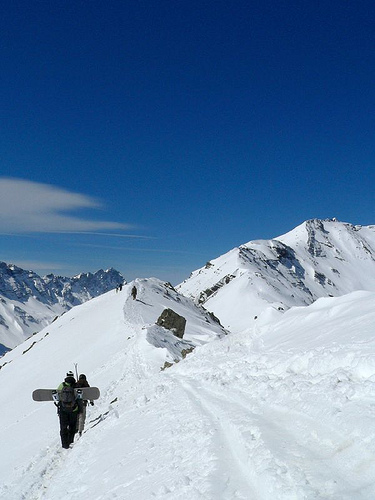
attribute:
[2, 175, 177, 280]
cloud — white 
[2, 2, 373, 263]
sky — beautiful, blue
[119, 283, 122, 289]
clothing — dark 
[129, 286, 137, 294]
coat — black 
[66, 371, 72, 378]
hat — white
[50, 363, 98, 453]
people — walking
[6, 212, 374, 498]
mountain — covered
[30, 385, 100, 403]
snowboard — gray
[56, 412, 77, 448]
pants — black 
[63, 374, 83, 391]
hat — black 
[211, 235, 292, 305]
snow — white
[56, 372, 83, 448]
man — black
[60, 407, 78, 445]
pants — black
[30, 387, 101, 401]
snowboard — grey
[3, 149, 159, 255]
cloud — white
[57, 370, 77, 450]
people — hiking 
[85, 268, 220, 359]
mountain — grey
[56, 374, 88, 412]
jacket — green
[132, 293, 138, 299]
pants — black